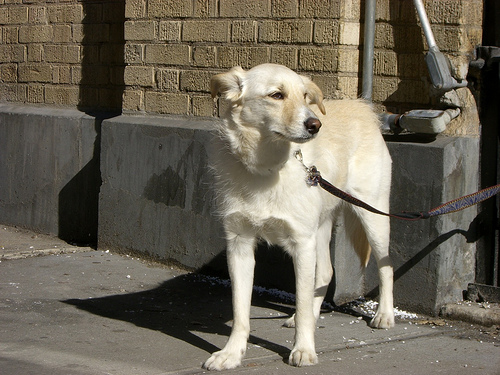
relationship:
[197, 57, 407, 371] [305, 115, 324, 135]
dog has nose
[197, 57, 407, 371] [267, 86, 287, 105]
dog has right eye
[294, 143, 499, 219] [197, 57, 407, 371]
leash attached to dog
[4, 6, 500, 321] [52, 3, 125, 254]
building has shadow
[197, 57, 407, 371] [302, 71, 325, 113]
dog has left ear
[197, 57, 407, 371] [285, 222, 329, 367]
dog has front left leg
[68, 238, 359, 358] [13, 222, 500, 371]
shadow on top of pavement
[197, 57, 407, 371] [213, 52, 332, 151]
dog has head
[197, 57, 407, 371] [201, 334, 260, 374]
dog has paw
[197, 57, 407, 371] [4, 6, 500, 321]
dog outside of building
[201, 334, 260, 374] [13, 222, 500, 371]
paw on pavement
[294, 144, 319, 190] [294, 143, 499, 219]
clasp attached to leash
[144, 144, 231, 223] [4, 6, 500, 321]
stain against building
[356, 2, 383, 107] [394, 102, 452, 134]
pole attached to box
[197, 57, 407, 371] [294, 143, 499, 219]
dog has leash